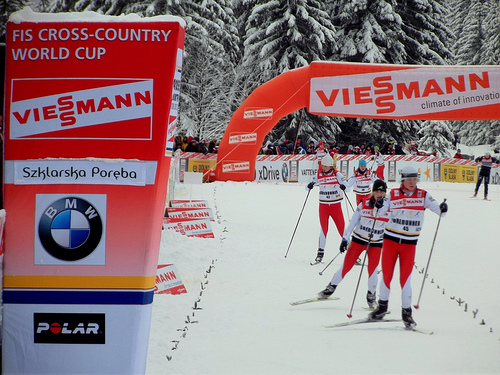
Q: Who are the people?
A: Skiers.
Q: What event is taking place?
A: FIS Cross-Country World Cup.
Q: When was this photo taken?
A: Daytime.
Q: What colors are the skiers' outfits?
A: Red and white.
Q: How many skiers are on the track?
A: Four.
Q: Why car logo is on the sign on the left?
A: BMW.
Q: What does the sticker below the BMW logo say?
A: POLAR.